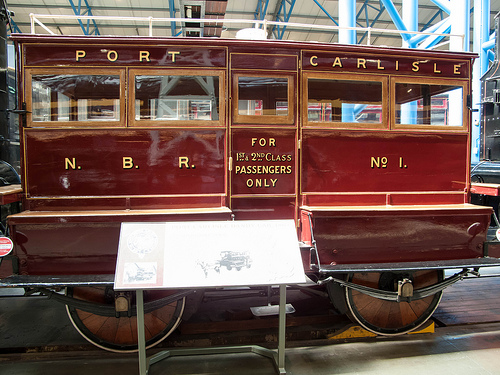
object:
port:
[68, 37, 186, 69]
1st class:
[230, 152, 253, 164]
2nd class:
[264, 148, 287, 162]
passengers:
[232, 163, 293, 174]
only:
[243, 176, 279, 187]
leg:
[133, 290, 149, 374]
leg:
[273, 283, 287, 373]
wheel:
[342, 268, 445, 339]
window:
[392, 81, 462, 124]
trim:
[468, 161, 499, 211]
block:
[322, 320, 376, 342]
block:
[405, 318, 437, 336]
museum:
[0, 0, 499, 374]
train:
[465, 16, 499, 232]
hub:
[397, 302, 417, 331]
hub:
[113, 318, 135, 343]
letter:
[72, 48, 88, 61]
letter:
[105, 48, 117, 62]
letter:
[166, 49, 179, 63]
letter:
[138, 50, 150, 64]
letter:
[308, 54, 318, 66]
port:
[72, 45, 183, 64]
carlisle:
[306, 52, 466, 74]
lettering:
[407, 59, 423, 72]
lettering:
[329, 54, 343, 68]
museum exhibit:
[0, 0, 499, 374]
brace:
[35, 287, 195, 317]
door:
[227, 51, 298, 211]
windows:
[16, 60, 129, 131]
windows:
[127, 62, 222, 126]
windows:
[232, 65, 295, 124]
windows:
[300, 69, 387, 131]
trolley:
[0, 32, 497, 342]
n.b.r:
[63, 155, 196, 173]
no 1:
[369, 154, 407, 171]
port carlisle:
[15, 36, 477, 76]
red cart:
[473, 182, 498, 197]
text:
[73, 45, 189, 69]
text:
[307, 56, 463, 76]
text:
[62, 156, 199, 173]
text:
[363, 153, 411, 170]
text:
[249, 133, 279, 147]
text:
[238, 149, 295, 163]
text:
[234, 165, 291, 177]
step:
[249, 302, 295, 317]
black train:
[477, 10, 500, 171]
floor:
[434, 275, 499, 326]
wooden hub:
[349, 291, 377, 312]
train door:
[479, 99, 499, 165]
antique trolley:
[0, 29, 499, 375]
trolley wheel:
[63, 280, 192, 355]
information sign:
[111, 218, 309, 291]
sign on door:
[226, 136, 302, 195]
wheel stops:
[403, 320, 436, 335]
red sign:
[0, 235, 14, 258]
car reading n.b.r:
[48, 138, 208, 191]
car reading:
[300, 50, 469, 79]